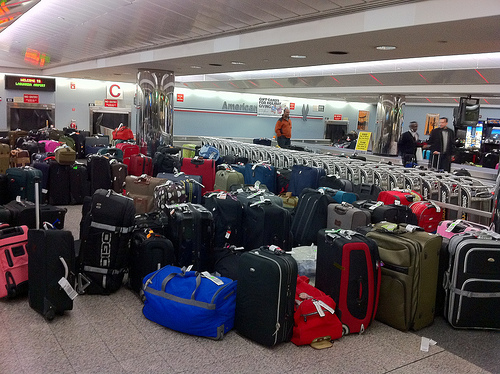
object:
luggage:
[363, 220, 443, 334]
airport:
[0, 0, 499, 374]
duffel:
[138, 263, 238, 343]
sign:
[354, 130, 373, 153]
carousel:
[290, 139, 498, 183]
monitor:
[457, 96, 481, 129]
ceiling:
[1, 0, 500, 111]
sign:
[105, 81, 125, 101]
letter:
[109, 84, 121, 99]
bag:
[289, 273, 344, 351]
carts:
[445, 175, 493, 232]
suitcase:
[326, 201, 373, 232]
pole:
[133, 66, 176, 158]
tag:
[199, 270, 224, 287]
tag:
[311, 301, 325, 320]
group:
[1, 123, 500, 350]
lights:
[287, 53, 308, 60]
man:
[426, 115, 457, 174]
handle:
[429, 150, 442, 172]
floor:
[2, 287, 500, 373]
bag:
[26, 221, 79, 323]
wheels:
[44, 308, 56, 323]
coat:
[273, 113, 293, 140]